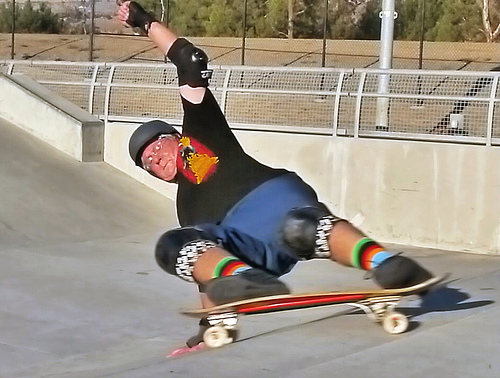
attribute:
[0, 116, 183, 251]
ramp — gray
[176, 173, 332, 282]
shorts — blue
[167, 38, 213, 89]
pad — black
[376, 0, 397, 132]
pole — gray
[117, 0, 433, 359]
man — skating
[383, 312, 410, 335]
wheel — white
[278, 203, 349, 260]
pad — black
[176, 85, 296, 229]
shirt — black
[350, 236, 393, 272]
sock — striped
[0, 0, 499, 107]
fence — wire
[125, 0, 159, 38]
guard — black